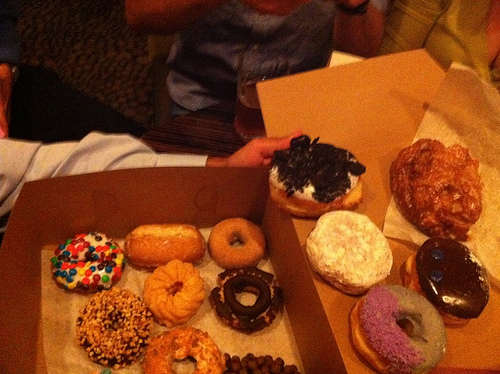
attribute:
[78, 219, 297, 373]
donuts — brown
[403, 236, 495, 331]
donut — chocolate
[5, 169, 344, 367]
box — brown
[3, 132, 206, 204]
sweater — white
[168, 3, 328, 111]
pants — black